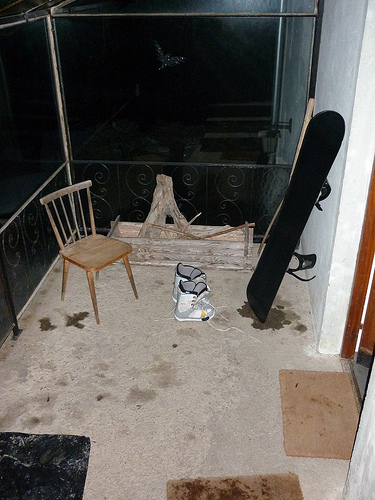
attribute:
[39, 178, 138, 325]
chair — empty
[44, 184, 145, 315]
chair — distressed, brown, wooden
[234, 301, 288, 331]
spot — wet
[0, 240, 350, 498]
floor — grey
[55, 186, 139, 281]
chair — brown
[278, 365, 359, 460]
rug — tan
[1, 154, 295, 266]
railing — wrought-iron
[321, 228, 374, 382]
trim — door trim, dark brown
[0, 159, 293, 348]
fence — black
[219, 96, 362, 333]
snowboard — black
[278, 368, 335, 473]
rug — area rug, light brown, dirty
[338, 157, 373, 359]
wooden door — open, wooden 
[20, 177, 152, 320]
chair — wooden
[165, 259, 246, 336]
boots — snowboard boots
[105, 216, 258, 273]
container — wooden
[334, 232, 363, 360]
door trim — dark brown, brown, dark